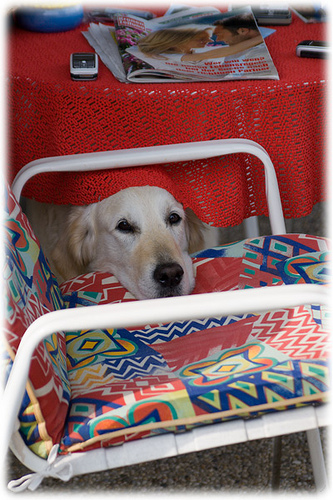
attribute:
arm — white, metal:
[12, 139, 281, 201]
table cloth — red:
[10, 2, 332, 227]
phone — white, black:
[69, 52, 99, 80]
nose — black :
[150, 259, 185, 289]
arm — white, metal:
[4, 274, 330, 478]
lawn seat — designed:
[4, 136, 332, 498]